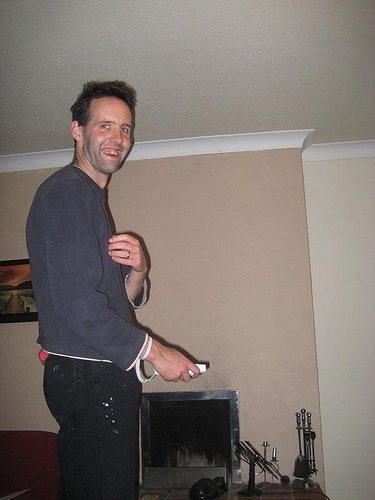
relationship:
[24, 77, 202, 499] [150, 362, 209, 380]
man holds remote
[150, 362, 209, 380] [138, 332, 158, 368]
remote attached to wrist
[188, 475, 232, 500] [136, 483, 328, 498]
object on floor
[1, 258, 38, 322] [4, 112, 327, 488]
painting on wall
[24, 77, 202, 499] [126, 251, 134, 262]
man wearing ring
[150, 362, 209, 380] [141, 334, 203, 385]
remote strapped to hand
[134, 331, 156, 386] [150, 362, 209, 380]
strap of remote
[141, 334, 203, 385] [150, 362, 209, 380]
hand holds remote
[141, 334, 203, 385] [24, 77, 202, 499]
hand of man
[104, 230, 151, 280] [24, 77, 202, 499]
hand of man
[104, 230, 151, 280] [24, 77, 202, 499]
left hand of man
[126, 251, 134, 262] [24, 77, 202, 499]
ring on man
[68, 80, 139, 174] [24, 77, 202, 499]
face of man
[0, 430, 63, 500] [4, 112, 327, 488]
couch by wall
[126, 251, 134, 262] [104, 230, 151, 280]
ring on hand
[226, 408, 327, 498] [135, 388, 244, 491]
tools of fireplace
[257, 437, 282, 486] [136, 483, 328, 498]
candleabra on top of floor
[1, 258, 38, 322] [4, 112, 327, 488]
picture on wall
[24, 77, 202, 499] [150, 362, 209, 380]
man holding controller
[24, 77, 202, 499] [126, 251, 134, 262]
man wearing wedding ring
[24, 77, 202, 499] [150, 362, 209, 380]
man holding wii controller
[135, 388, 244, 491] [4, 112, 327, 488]
fireplace against wall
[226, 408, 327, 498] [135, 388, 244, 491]
tools next to fireplace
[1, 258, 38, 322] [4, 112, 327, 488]
picture hanging on wall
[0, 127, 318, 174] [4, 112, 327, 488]
moulding on wall